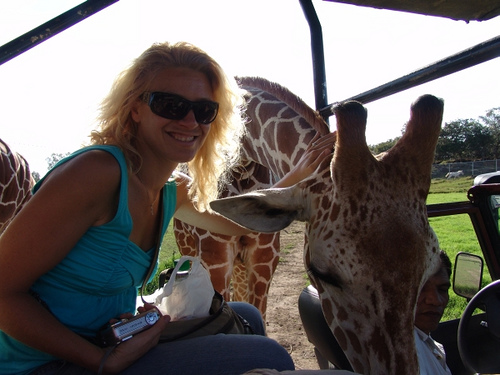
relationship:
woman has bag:
[1, 38, 351, 375] [132, 279, 247, 346]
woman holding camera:
[1, 38, 351, 375] [101, 307, 159, 349]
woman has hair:
[1, 38, 351, 375] [92, 37, 257, 222]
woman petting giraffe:
[1, 38, 351, 375] [169, 69, 457, 375]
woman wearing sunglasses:
[1, 38, 351, 375] [144, 89, 230, 125]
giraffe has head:
[169, 69, 457, 375] [285, 90, 462, 375]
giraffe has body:
[169, 69, 457, 375] [165, 75, 296, 328]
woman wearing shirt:
[1, 38, 351, 375] [0, 137, 183, 366]